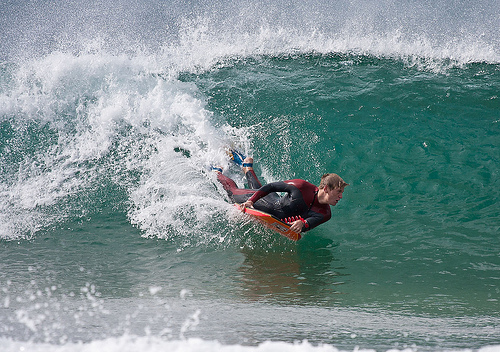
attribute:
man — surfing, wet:
[214, 158, 345, 231]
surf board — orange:
[237, 208, 300, 243]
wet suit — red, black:
[213, 172, 334, 230]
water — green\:
[358, 112, 498, 243]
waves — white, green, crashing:
[3, 37, 499, 88]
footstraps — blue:
[207, 150, 250, 173]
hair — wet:
[320, 173, 349, 188]